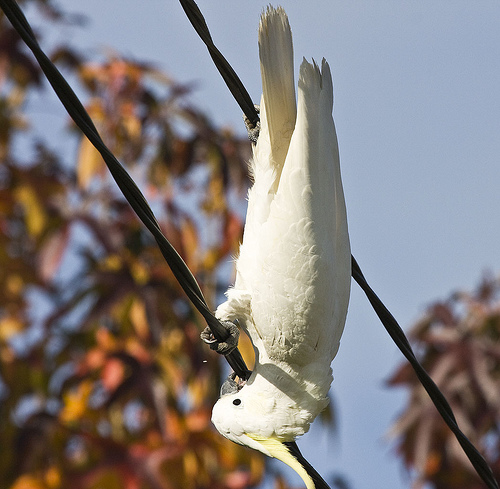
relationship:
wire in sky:
[7, 1, 258, 129] [150, 2, 260, 103]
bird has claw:
[195, 6, 352, 486] [199, 315, 243, 349]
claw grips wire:
[199, 315, 243, 349] [7, 1, 258, 129]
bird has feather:
[195, 6, 352, 486] [251, 433, 322, 489]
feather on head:
[251, 433, 322, 489] [211, 375, 316, 489]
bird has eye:
[195, 6, 352, 486] [234, 399, 240, 406]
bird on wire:
[195, 6, 352, 486] [7, 1, 258, 129]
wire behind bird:
[7, 1, 258, 129] [195, 6, 352, 486]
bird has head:
[195, 6, 352, 486] [211, 375, 316, 489]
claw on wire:
[199, 315, 243, 349] [7, 1, 258, 129]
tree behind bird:
[5, 81, 242, 485] [195, 6, 352, 486]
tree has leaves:
[5, 81, 242, 485] [7, 302, 196, 485]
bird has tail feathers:
[195, 6, 352, 486] [256, 10, 342, 178]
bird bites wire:
[195, 6, 352, 486] [7, 1, 258, 129]